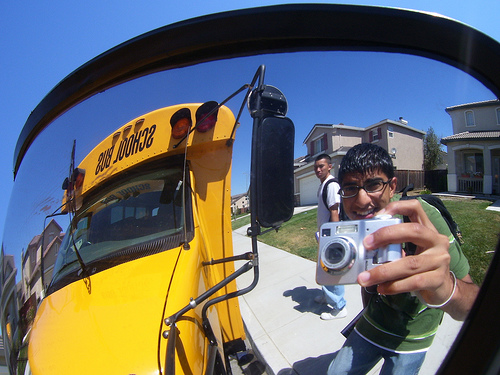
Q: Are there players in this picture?
A: No, there are no players.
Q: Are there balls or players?
A: No, there are no players or balls.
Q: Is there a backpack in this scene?
A: Yes, there is a backpack.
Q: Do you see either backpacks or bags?
A: Yes, there is a backpack.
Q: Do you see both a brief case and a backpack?
A: No, there is a backpack but no briefcases.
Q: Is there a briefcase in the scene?
A: No, there are no briefcases.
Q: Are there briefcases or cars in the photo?
A: No, there are no briefcases or cars.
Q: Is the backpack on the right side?
A: Yes, the backpack is on the right of the image.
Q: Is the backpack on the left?
A: No, the backpack is on the right of the image.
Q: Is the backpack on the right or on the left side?
A: The backpack is on the right of the image.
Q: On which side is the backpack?
A: The backpack is on the right of the image.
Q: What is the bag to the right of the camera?
A: The bag is a backpack.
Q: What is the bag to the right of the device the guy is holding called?
A: The bag is a backpack.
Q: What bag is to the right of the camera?
A: The bag is a backpack.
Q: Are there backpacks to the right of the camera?
A: Yes, there is a backpack to the right of the camera.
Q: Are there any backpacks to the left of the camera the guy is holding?
A: No, the backpack is to the right of the camera.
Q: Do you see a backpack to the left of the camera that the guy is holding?
A: No, the backpack is to the right of the camera.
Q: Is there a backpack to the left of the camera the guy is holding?
A: No, the backpack is to the right of the camera.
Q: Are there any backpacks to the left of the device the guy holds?
A: No, the backpack is to the right of the camera.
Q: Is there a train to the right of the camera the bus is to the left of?
A: No, there is a backpack to the right of the camera.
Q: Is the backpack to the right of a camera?
A: Yes, the backpack is to the right of a camera.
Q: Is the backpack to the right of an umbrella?
A: No, the backpack is to the right of a camera.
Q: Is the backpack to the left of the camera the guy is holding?
A: No, the backpack is to the right of the camera.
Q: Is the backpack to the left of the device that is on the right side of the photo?
A: No, the backpack is to the right of the camera.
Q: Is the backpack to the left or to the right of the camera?
A: The backpack is to the right of the camera.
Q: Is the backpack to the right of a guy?
A: Yes, the backpack is to the right of a guy.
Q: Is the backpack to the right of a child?
A: No, the backpack is to the right of a guy.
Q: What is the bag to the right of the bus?
A: The bag is a backpack.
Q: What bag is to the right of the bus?
A: The bag is a backpack.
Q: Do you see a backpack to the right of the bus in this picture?
A: Yes, there is a backpack to the right of the bus.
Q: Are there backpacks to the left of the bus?
A: No, the backpack is to the right of the bus.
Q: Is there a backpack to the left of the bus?
A: No, the backpack is to the right of the bus.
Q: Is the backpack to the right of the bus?
A: Yes, the backpack is to the right of the bus.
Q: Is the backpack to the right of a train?
A: No, the backpack is to the right of the bus.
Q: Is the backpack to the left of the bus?
A: No, the backpack is to the right of the bus.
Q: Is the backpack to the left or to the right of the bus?
A: The backpack is to the right of the bus.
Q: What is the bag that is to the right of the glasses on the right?
A: The bag is a backpack.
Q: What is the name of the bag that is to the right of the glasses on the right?
A: The bag is a backpack.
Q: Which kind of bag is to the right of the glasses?
A: The bag is a backpack.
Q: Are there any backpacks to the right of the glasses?
A: Yes, there is a backpack to the right of the glasses.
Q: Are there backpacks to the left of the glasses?
A: No, the backpack is to the right of the glasses.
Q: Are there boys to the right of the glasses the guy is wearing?
A: No, there is a backpack to the right of the glasses.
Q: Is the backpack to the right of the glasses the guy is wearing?
A: Yes, the backpack is to the right of the glasses.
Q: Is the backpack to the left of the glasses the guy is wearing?
A: No, the backpack is to the right of the glasses.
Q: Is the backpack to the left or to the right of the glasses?
A: The backpack is to the right of the glasses.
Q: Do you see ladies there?
A: No, there are no ladies.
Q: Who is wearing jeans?
A: The guy is wearing jeans.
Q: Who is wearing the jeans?
A: The guy is wearing jeans.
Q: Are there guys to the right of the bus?
A: Yes, there is a guy to the right of the bus.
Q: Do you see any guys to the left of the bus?
A: No, the guy is to the right of the bus.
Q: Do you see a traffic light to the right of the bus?
A: No, there is a guy to the right of the bus.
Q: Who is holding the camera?
A: The guy is holding the camera.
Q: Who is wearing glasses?
A: The guy is wearing glasses.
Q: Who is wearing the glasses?
A: The guy is wearing glasses.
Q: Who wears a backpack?
A: The guy wears a backpack.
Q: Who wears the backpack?
A: The guy wears a backpack.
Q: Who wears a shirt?
A: The guy wears a shirt.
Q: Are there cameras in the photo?
A: Yes, there is a camera.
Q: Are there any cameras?
A: Yes, there is a camera.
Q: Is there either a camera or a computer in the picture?
A: Yes, there is a camera.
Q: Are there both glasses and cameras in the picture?
A: Yes, there are both a camera and glasses.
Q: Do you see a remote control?
A: No, there are no remote controls.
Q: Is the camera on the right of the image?
A: Yes, the camera is on the right of the image.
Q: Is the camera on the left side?
A: No, the camera is on the right of the image.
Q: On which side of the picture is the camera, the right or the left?
A: The camera is on the right of the image.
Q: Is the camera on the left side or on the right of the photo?
A: The camera is on the right of the image.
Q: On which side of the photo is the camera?
A: The camera is on the right of the image.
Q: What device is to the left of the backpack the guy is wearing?
A: The device is a camera.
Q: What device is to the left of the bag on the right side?
A: The device is a camera.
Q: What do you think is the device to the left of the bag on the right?
A: The device is a camera.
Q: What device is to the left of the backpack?
A: The device is a camera.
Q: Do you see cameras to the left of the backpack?
A: Yes, there is a camera to the left of the backpack.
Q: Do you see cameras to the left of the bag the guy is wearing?
A: Yes, there is a camera to the left of the backpack.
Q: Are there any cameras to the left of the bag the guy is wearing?
A: Yes, there is a camera to the left of the backpack.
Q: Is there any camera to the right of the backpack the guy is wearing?
A: No, the camera is to the left of the backpack.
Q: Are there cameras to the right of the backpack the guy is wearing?
A: No, the camera is to the left of the backpack.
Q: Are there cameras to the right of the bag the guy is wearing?
A: No, the camera is to the left of the backpack.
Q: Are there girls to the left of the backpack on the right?
A: No, there is a camera to the left of the backpack.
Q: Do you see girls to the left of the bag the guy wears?
A: No, there is a camera to the left of the backpack.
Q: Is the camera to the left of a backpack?
A: Yes, the camera is to the left of a backpack.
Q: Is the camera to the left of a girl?
A: No, the camera is to the left of a backpack.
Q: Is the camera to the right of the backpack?
A: No, the camera is to the left of the backpack.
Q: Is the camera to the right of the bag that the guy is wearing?
A: No, the camera is to the left of the backpack.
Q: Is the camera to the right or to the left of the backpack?
A: The camera is to the left of the backpack.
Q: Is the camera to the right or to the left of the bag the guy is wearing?
A: The camera is to the left of the backpack.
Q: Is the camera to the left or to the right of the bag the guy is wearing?
A: The camera is to the left of the backpack.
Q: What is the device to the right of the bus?
A: The device is a camera.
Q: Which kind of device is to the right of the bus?
A: The device is a camera.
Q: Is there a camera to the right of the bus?
A: Yes, there is a camera to the right of the bus.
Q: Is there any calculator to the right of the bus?
A: No, there is a camera to the right of the bus.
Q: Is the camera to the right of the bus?
A: Yes, the camera is to the right of the bus.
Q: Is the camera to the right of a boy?
A: No, the camera is to the right of the bus.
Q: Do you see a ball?
A: No, there are no balls.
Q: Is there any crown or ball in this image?
A: No, there are no balls or crowns.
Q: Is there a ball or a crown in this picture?
A: No, there are no balls or crowns.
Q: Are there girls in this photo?
A: No, there are no girls.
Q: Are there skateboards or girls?
A: No, there are no girls or skateboards.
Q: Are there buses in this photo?
A: Yes, there is a bus.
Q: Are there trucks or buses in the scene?
A: Yes, there is a bus.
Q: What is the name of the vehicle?
A: The vehicle is a bus.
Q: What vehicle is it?
A: The vehicle is a bus.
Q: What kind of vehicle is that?
A: This is a bus.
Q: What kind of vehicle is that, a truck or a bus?
A: This is a bus.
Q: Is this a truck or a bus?
A: This is a bus.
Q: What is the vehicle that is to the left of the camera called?
A: The vehicle is a bus.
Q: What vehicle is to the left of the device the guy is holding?
A: The vehicle is a bus.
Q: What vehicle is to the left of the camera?
A: The vehicle is a bus.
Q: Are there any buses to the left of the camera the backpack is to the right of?
A: Yes, there is a bus to the left of the camera.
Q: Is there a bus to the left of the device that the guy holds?
A: Yes, there is a bus to the left of the camera.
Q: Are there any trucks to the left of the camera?
A: No, there is a bus to the left of the camera.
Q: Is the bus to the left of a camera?
A: Yes, the bus is to the left of a camera.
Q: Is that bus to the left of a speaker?
A: No, the bus is to the left of a camera.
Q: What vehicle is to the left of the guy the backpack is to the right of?
A: The vehicle is a bus.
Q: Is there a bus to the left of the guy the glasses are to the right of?
A: Yes, there is a bus to the left of the guy.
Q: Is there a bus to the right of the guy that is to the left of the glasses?
A: No, the bus is to the left of the guy.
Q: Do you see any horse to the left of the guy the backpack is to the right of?
A: No, there is a bus to the left of the guy.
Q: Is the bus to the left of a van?
A: No, the bus is to the left of a guy.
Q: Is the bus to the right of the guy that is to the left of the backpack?
A: No, the bus is to the left of the guy.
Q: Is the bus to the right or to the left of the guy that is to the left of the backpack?
A: The bus is to the left of the guy.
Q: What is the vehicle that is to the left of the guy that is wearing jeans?
A: The vehicle is a bus.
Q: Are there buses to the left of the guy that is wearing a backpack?
A: Yes, there is a bus to the left of the guy.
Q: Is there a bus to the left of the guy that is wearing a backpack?
A: Yes, there is a bus to the left of the guy.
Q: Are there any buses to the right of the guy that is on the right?
A: No, the bus is to the left of the guy.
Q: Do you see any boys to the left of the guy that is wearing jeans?
A: No, there is a bus to the left of the guy.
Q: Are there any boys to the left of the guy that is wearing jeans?
A: No, there is a bus to the left of the guy.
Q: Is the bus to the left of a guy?
A: Yes, the bus is to the left of a guy.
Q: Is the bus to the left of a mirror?
A: No, the bus is to the left of a guy.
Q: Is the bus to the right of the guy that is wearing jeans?
A: No, the bus is to the left of the guy.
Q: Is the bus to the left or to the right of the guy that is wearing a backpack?
A: The bus is to the left of the guy.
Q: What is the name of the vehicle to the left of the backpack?
A: The vehicle is a bus.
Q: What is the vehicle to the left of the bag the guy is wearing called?
A: The vehicle is a bus.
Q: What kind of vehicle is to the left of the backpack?
A: The vehicle is a bus.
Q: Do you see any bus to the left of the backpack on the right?
A: Yes, there is a bus to the left of the backpack.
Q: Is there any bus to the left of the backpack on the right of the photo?
A: Yes, there is a bus to the left of the backpack.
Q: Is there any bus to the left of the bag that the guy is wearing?
A: Yes, there is a bus to the left of the backpack.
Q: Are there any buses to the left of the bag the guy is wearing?
A: Yes, there is a bus to the left of the backpack.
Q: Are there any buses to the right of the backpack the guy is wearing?
A: No, the bus is to the left of the backpack.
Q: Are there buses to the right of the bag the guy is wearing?
A: No, the bus is to the left of the backpack.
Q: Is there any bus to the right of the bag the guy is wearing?
A: No, the bus is to the left of the backpack.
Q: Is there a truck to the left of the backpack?
A: No, there is a bus to the left of the backpack.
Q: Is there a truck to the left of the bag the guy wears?
A: No, there is a bus to the left of the backpack.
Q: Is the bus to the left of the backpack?
A: Yes, the bus is to the left of the backpack.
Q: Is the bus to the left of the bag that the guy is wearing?
A: Yes, the bus is to the left of the backpack.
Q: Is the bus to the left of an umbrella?
A: No, the bus is to the left of the backpack.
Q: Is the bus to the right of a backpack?
A: No, the bus is to the left of a backpack.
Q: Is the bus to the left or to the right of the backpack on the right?
A: The bus is to the left of the backpack.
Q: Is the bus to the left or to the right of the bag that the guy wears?
A: The bus is to the left of the backpack.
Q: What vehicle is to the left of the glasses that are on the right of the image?
A: The vehicle is a bus.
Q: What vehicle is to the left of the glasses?
A: The vehicle is a bus.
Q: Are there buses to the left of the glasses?
A: Yes, there is a bus to the left of the glasses.